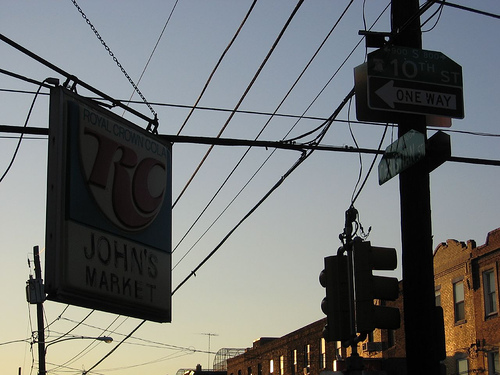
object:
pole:
[389, 0, 449, 375]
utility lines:
[0, 124, 500, 169]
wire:
[171, 1, 255, 144]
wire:
[171, 0, 301, 207]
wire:
[171, 1, 351, 253]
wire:
[171, 1, 389, 270]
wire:
[170, 89, 352, 294]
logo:
[71, 105, 169, 251]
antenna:
[202, 331, 218, 371]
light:
[43, 335, 113, 356]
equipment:
[25, 274, 46, 305]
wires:
[0, 89, 500, 139]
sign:
[364, 46, 465, 120]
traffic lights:
[317, 241, 356, 347]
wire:
[349, 123, 386, 205]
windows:
[268, 359, 274, 373]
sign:
[46, 80, 175, 325]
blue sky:
[0, 0, 500, 315]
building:
[175, 225, 500, 374]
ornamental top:
[431, 239, 476, 275]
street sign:
[377, 129, 426, 185]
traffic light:
[351, 237, 402, 339]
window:
[480, 265, 499, 318]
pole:
[43, 336, 95, 354]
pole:
[32, 245, 48, 375]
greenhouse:
[212, 347, 248, 372]